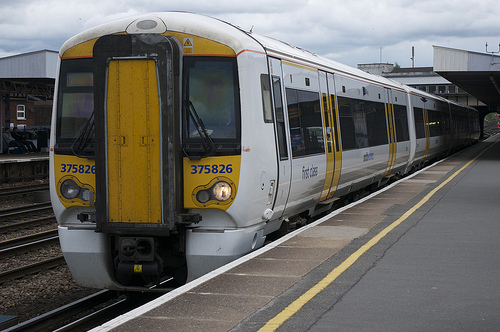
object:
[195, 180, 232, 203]
headlight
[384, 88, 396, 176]
train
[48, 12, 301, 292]
lead car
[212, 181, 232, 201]
light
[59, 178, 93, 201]
headlight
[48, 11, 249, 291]
train front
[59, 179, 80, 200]
light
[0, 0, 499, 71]
sky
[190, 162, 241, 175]
numbers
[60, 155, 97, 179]
numbers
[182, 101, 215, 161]
wiper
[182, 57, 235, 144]
windshield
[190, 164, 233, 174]
number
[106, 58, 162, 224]
door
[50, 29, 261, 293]
end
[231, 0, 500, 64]
clouds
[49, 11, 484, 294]
large train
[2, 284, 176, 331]
train track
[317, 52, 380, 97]
ground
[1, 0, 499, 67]
clouds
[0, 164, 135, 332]
tracks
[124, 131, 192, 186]
floor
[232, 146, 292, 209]
wall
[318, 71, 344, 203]
doors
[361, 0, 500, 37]
cloud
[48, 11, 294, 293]
train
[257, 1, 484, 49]
sky